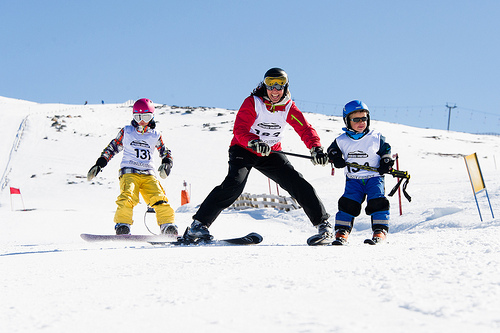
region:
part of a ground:
[226, 269, 264, 331]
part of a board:
[238, 216, 270, 250]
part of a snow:
[243, 245, 268, 291]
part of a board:
[236, 212, 292, 277]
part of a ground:
[273, 254, 307, 296]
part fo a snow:
[274, 240, 307, 285]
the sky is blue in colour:
[78, 20, 240, 87]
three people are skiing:
[90, 55, 425, 267]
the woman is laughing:
[228, 71, 298, 128]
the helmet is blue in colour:
[330, 90, 375, 110]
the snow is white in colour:
[85, 254, 355, 331]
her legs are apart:
[175, 138, 351, 264]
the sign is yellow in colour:
[442, 142, 499, 226]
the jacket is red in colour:
[222, 58, 323, 165]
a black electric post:
[409, 90, 479, 137]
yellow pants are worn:
[114, 168, 178, 234]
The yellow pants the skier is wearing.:
[115, 167, 176, 234]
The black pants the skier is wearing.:
[194, 131, 329, 223]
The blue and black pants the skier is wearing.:
[326, 168, 404, 237]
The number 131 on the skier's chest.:
[131, 143, 158, 163]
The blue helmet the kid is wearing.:
[340, 96, 368, 122]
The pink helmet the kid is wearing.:
[130, 96, 151, 112]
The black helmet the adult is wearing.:
[262, 67, 288, 77]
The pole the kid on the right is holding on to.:
[260, 137, 413, 192]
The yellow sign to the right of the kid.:
[455, 130, 498, 220]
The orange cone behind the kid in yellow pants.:
[175, 168, 205, 213]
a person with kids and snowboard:
[86, 58, 423, 264]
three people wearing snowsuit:
[116, 88, 398, 240]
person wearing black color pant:
[196, 130, 328, 238]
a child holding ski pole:
[336, 100, 393, 252]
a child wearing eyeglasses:
[346, 114, 373, 126]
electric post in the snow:
[426, 86, 466, 142]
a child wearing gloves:
[154, 158, 176, 181]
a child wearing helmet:
[128, 97, 156, 122]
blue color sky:
[104, 19, 479, 85]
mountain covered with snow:
[46, 123, 445, 275]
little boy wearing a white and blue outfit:
[325, 91, 411, 244]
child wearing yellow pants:
[112, 171, 187, 238]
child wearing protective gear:
[321, 100, 424, 246]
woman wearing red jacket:
[227, 88, 332, 165]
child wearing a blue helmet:
[340, 100, 382, 139]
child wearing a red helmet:
[132, 94, 152, 112]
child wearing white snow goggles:
[128, 107, 161, 126]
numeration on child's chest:
[128, 144, 157, 162]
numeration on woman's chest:
[249, 115, 286, 145]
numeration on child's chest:
[340, 148, 385, 171]